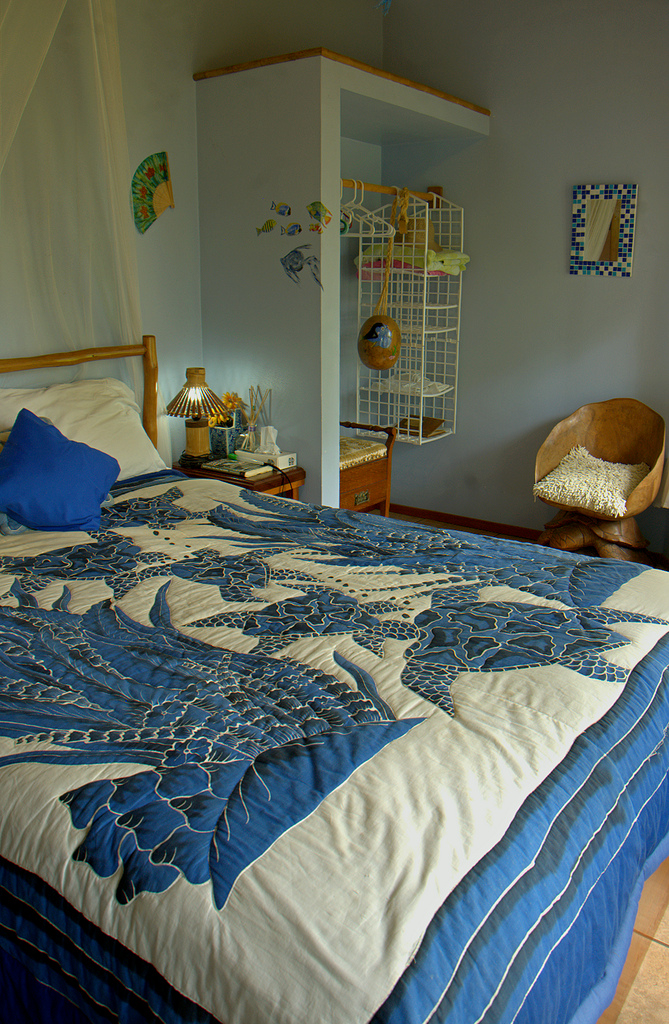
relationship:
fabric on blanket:
[123, 798, 188, 846] [0, 459, 668, 1020]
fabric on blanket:
[193, 751, 250, 806] [0, 459, 668, 1020]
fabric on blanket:
[322, 638, 414, 728] [0, 459, 668, 1020]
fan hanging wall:
[127, 153, 182, 230] [2, 2, 236, 448]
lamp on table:
[167, 357, 231, 473] [177, 463, 304, 497]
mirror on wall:
[564, 181, 638, 272] [359, 9, 648, 477]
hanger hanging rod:
[343, 185, 393, 253] [328, 162, 456, 214]